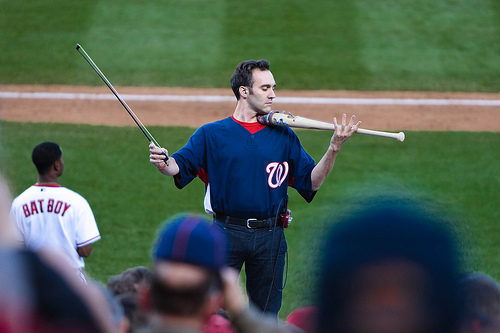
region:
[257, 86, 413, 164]
This is a baseball bat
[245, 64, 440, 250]
This is a bat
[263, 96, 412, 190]
The bat is made of wood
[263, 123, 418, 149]
The bat is light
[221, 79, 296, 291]
The shirt is blue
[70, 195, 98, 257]
The shirt is white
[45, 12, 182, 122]
This is a violin bow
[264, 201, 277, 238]
This is a belt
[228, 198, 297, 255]
The belt is black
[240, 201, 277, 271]
The belt is made of leather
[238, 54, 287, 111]
Person has dark hair.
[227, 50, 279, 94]
Person has short hair.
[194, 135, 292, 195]
Person wearing blue shirt.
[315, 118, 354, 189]
Person holding baseball bat like violin.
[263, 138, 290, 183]
White W on jersey.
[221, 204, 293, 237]
Man wearing black belt.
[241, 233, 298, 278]
Man wearing blue jeans.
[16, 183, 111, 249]
Bat boy wearing white jersey.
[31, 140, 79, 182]
Man has dark short hair.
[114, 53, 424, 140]
White line marking field.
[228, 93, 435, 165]
man holding a baseball bat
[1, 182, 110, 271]
man wearing a jersey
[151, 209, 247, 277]
man wearing a blue hat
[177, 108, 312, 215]
man wearing a blue shirt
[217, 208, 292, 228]
man wearing a black belt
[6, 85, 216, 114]
white line in dirt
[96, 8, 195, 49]
green grassy baseball field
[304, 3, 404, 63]
green grassy baseball field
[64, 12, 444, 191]
man holding bat like a violin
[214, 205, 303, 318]
man wearing blue jeans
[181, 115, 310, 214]
the shirt is blue in color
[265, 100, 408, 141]
the baseball bat is wooden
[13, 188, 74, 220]
the batboy is on the shirt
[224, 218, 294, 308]
the pants are blue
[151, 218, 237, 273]
the hat is blue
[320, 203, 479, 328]
the photo is blurred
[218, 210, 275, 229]
the belt is black in color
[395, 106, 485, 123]
the ground is brown in color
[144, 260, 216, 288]
the head is bladheaded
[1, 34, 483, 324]
the people are in a baseball park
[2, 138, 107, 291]
A young man wearing a shirt that says "bat boy"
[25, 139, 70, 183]
The young man's head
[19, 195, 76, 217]
"bat boy" written on the back of the young man's shirt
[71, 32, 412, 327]
A man about to pretend to play a baseball bat like a violin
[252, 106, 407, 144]
The baseball bat in the man's left hand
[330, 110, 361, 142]
The man's left hand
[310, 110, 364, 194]
The man's left hand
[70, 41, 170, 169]
The bow in the man's right hand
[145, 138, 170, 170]
The man's right hand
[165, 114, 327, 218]
The man's blue shirt